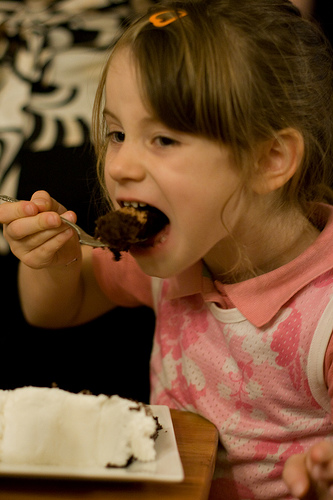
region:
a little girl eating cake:
[2, 5, 332, 459]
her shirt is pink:
[92, 192, 331, 497]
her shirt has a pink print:
[153, 256, 329, 498]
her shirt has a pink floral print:
[148, 241, 330, 498]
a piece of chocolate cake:
[77, 197, 187, 283]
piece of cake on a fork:
[9, 183, 170, 275]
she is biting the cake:
[85, 170, 209, 293]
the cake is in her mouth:
[86, 181, 176, 268]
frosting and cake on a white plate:
[0, 374, 197, 491]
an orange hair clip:
[143, 2, 194, 32]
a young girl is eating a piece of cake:
[5, 22, 282, 309]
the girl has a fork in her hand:
[2, 181, 145, 267]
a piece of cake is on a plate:
[1, 385, 161, 471]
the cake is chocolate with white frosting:
[3, 378, 167, 468]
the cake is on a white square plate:
[1, 377, 187, 485]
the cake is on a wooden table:
[1, 379, 236, 496]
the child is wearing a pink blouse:
[90, 248, 332, 484]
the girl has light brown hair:
[89, 5, 332, 241]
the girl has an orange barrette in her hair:
[105, 6, 201, 51]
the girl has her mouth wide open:
[92, 186, 184, 264]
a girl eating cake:
[62, 23, 280, 339]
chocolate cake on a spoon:
[80, 209, 155, 252]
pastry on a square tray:
[17, 386, 183, 486]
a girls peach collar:
[226, 280, 331, 305]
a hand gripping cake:
[5, 196, 93, 267]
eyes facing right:
[105, 119, 191, 152]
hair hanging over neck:
[223, 110, 284, 277]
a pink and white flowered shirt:
[184, 322, 305, 404]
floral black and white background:
[14, 9, 85, 144]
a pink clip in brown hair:
[143, 6, 195, 32]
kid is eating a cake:
[51, 76, 193, 293]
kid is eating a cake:
[21, 97, 207, 328]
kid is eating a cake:
[6, 95, 237, 310]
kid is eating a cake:
[17, 88, 243, 358]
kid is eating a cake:
[24, 87, 222, 318]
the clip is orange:
[141, 9, 232, 59]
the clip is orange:
[133, 3, 221, 62]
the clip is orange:
[139, 4, 201, 46]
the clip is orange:
[137, 6, 219, 55]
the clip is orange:
[137, 8, 213, 41]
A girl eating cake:
[1, 1, 331, 338]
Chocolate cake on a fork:
[0, 187, 156, 264]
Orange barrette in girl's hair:
[150, 8, 188, 32]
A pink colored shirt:
[90, 197, 331, 497]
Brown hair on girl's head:
[87, 1, 330, 273]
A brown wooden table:
[1, 407, 220, 499]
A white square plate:
[2, 383, 186, 489]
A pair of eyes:
[100, 122, 186, 158]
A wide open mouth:
[101, 191, 184, 259]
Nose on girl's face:
[104, 129, 151, 192]